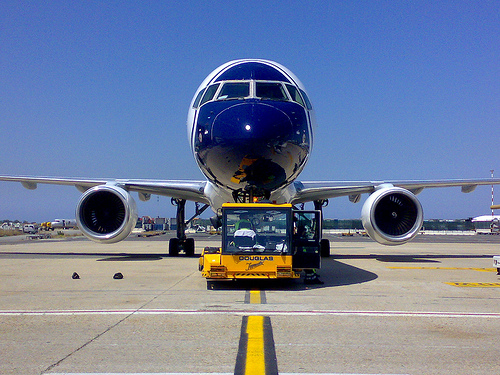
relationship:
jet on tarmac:
[0, 58, 499, 257] [0, 280, 480, 369]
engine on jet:
[359, 185, 424, 246] [0, 58, 499, 257]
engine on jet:
[353, 181, 431, 248] [0, 58, 499, 257]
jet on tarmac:
[0, 58, 499, 257] [1, 237, 169, 373]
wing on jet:
[0, 172, 208, 209] [0, 58, 499, 257]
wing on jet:
[299, 176, 499, 246] [0, 58, 499, 257]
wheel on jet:
[166, 236, 183, 256] [0, 58, 499, 257]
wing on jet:
[2, 171, 207, 243] [0, 58, 499, 257]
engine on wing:
[359, 185, 424, 246] [299, 176, 499, 246]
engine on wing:
[76, 185, 135, 240] [2, 171, 207, 243]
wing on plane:
[0, 172, 208, 209] [46, 47, 466, 323]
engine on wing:
[76, 185, 135, 240] [0, 172, 208, 209]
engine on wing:
[359, 185, 424, 246] [0, 172, 208, 209]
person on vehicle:
[235, 220, 257, 254] [199, 202, 327, 287]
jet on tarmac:
[0, 58, 499, 257] [3, 284, 472, 373]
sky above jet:
[0, 0, 499, 226] [0, 58, 499, 257]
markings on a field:
[236, 292, 278, 372] [9, 250, 488, 372]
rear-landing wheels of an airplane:
[167, 235, 197, 256] [12, 49, 493, 256]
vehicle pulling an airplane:
[198, 199, 305, 286] [12, 49, 493, 256]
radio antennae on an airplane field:
[488, 169, 499, 215] [7, 219, 494, 371]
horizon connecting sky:
[2, 215, 499, 235] [2, 2, 496, 220]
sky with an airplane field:
[2, 2, 496, 220] [2, 235, 499, 371]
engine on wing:
[76, 185, 135, 240] [1, 175, 210, 205]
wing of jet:
[299, 176, 499, 246] [0, 58, 499, 257]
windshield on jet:
[203, 80, 305, 109] [0, 58, 499, 257]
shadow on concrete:
[323, 247, 498, 263] [4, 224, 497, 372]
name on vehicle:
[238, 254, 274, 261] [194, 198, 326, 291]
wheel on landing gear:
[166, 236, 183, 256] [167, 198, 209, 255]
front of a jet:
[185, 55, 314, 202] [0, 58, 499, 257]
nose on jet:
[206, 97, 303, 187] [0, 58, 499, 257]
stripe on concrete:
[230, 287, 279, 371] [2, 286, 211, 373]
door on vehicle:
[283, 205, 324, 276] [198, 202, 331, 290]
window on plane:
[282, 84, 308, 104] [0, 27, 470, 261]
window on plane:
[253, 80, 289, 100] [0, 27, 470, 261]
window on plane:
[215, 79, 251, 100] [0, 27, 470, 261]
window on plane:
[197, 81, 220, 103] [0, 27, 470, 261]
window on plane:
[190, 85, 205, 109] [0, 27, 470, 261]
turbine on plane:
[372, 190, 420, 237] [59, 32, 441, 298]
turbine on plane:
[78, 189, 123, 237] [59, 32, 441, 298]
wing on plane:
[299, 176, 499, 246] [49, 27, 395, 267]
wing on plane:
[0, 172, 208, 209] [49, 27, 395, 267]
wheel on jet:
[166, 233, 195, 256] [0, 58, 499, 257]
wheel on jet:
[313, 235, 333, 255] [0, 58, 499, 257]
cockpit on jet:
[188, 80, 306, 105] [0, 58, 499, 257]